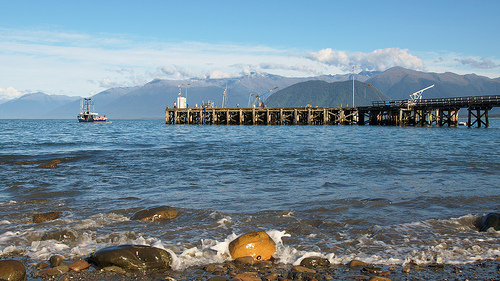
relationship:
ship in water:
[78, 94, 109, 125] [0, 115, 499, 271]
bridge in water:
[162, 96, 499, 125] [0, 115, 499, 271]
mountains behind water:
[7, 66, 500, 122] [0, 115, 499, 271]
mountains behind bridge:
[7, 66, 500, 122] [162, 96, 499, 125]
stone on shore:
[92, 243, 173, 267] [1, 223, 500, 280]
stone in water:
[92, 243, 173, 267] [0, 115, 499, 271]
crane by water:
[407, 80, 437, 102] [0, 115, 499, 271]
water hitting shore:
[0, 115, 499, 271] [1, 223, 500, 280]